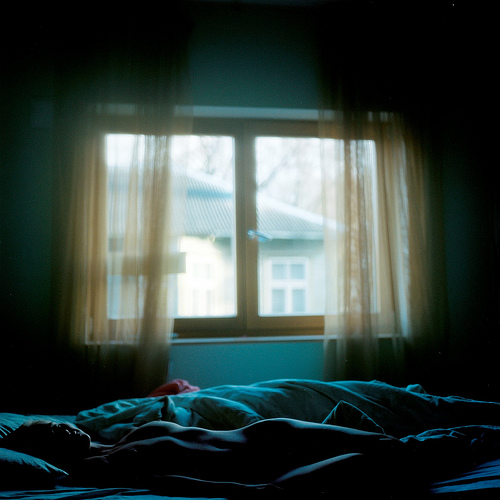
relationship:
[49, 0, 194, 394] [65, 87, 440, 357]
curtain on window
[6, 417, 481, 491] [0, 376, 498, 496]
girl laying on bed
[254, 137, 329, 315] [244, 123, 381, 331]
glass in window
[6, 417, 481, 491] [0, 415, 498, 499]
girl on bed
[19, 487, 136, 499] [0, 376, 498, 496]
sheet on bed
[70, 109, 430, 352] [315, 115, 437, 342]
window has curtains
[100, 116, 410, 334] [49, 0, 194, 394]
window has curtain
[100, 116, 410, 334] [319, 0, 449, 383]
window has curtain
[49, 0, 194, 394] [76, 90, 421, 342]
curtain on window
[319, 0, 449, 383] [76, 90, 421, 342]
curtain on window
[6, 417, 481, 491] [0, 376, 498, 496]
girl on bed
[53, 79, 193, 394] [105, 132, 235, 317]
curtain on window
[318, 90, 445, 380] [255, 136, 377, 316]
curtain on window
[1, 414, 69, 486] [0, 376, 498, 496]
pillow on bed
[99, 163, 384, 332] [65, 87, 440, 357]
house visible through window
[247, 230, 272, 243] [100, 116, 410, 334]
handle on window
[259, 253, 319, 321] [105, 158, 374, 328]
window next to house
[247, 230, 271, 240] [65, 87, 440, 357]
handle in window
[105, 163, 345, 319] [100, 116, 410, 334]
house seen through window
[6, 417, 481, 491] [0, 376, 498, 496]
girl in bed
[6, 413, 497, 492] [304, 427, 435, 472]
girl in bed